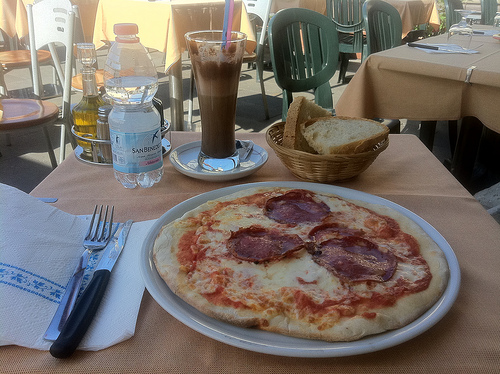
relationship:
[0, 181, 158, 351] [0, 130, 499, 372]
napkin on table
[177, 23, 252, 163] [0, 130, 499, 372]
glass on table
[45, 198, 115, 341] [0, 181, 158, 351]
utensils on napkin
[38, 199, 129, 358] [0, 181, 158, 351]
fork on napkin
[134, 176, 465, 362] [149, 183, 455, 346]
plate under pizza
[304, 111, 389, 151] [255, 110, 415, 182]
bread in basket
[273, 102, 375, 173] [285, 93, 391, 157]
basket holding bread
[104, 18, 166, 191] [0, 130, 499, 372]
bottle on table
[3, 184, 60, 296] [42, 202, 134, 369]
napkins under utensils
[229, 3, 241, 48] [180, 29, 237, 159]
straw in cup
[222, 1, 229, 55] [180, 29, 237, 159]
straw in cup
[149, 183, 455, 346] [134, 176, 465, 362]
pizza on plate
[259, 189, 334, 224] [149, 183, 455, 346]
pepperoni on pizza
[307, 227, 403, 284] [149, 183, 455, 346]
pepperoni on pizza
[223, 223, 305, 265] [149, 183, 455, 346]
pepperoni on pizza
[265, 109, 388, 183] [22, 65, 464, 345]
basket on table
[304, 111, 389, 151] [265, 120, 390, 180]
bread in basket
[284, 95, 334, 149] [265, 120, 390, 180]
bread in basket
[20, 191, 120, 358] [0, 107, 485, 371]
fork on table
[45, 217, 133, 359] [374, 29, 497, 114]
knife on table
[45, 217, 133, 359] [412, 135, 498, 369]
knife on table